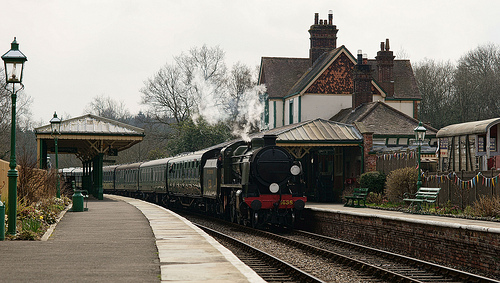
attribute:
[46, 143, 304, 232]
train — black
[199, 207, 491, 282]
tracks — metal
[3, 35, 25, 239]
street lamp — green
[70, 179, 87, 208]
bench — green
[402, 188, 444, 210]
bench — green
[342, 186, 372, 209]
bench — green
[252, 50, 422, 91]
roof — grey, gray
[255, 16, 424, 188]
building — white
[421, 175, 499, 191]
flags — multi-colored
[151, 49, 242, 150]
tree — large, bare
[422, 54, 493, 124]
trees — bare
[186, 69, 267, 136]
smoke — white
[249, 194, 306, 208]
frontpiece — red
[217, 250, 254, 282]
platform edge — white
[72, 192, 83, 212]
trash can — green